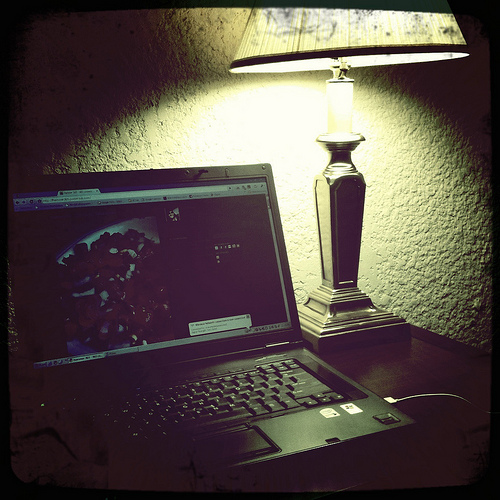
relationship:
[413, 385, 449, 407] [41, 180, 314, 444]
cord in laptop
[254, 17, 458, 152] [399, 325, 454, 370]
lamp on table